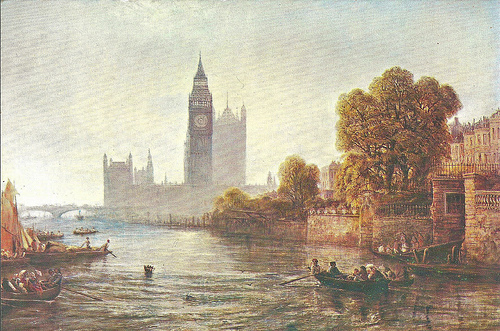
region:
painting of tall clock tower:
[183, 48, 217, 211]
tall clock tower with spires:
[187, 48, 217, 218]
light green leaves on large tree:
[329, 55, 463, 205]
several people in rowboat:
[282, 252, 389, 296]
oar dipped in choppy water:
[56, 272, 106, 307]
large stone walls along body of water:
[209, 168, 496, 260]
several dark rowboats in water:
[3, 184, 125, 316]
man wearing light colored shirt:
[304, 256, 324, 289]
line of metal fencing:
[440, 159, 499, 175]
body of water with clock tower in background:
[129, 42, 246, 317]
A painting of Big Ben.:
[181, 44, 217, 201]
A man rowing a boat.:
[284, 254, 333, 287]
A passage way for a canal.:
[412, 169, 482, 269]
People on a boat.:
[3, 266, 83, 308]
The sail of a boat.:
[0, 179, 41, 265]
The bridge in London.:
[26, 154, 168, 224]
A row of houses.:
[448, 109, 496, 173]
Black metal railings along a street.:
[440, 157, 498, 179]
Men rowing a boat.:
[75, 231, 120, 266]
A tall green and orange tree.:
[333, 60, 455, 227]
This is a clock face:
[188, 113, 211, 131]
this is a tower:
[177, 44, 228, 199]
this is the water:
[159, 230, 217, 272]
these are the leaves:
[368, 107, 408, 142]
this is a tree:
[316, 61, 464, 232]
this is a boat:
[290, 261, 432, 309]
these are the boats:
[13, 207, 127, 307]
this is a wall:
[306, 198, 401, 255]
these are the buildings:
[84, 53, 266, 223]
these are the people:
[315, 261, 390, 284]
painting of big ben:
[162, 29, 271, 210]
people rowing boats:
[5, 220, 428, 310]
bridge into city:
[0, 190, 143, 232]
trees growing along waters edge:
[292, 80, 482, 202]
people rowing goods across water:
[0, 234, 145, 267]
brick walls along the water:
[214, 203, 360, 248]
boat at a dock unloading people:
[368, 220, 483, 299]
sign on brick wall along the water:
[435, 185, 480, 217]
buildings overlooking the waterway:
[447, 93, 490, 183]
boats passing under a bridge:
[19, 213, 88, 220]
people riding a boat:
[301, 248, 407, 309]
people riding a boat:
[343, 249, 415, 297]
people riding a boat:
[9, 257, 84, 303]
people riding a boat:
[31, 237, 149, 276]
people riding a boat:
[42, 221, 115, 244]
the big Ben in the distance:
[182, 59, 244, 216]